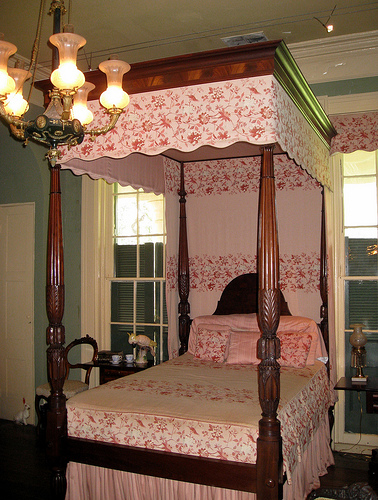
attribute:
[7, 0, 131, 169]
chandelier — ornate, old fashioned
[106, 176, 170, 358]
window — white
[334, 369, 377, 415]
table — brown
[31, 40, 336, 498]
bed — wooden, four poster, old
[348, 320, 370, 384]
lamp — unlit, old, small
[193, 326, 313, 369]
pillows — pink, floral, red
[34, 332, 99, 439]
chair — wooden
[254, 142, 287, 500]
post — wooden, carved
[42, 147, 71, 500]
post — wooden, carved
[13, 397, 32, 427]
door stop — a bunny, a rabbit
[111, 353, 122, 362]
teacup — white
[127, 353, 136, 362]
teacup — white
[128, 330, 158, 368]
bird — ceramic, small, glass, white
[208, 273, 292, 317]
headboard — wooden, brown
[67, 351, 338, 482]
bedspread — pink, red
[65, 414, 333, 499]
bed skirt — pink, ruffled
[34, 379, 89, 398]
seat — white, padded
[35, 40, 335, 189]
canopy — pink, red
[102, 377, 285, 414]
flowers — pink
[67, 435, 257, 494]
footboard — brown, small